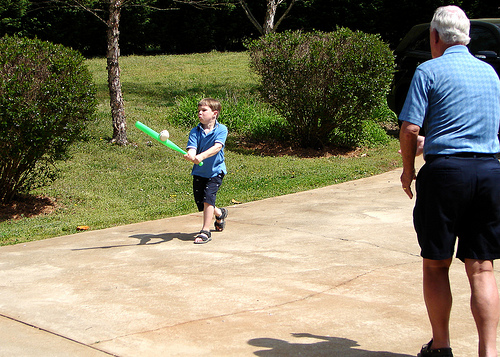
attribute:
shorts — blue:
[189, 168, 225, 211]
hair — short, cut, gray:
[436, 4, 467, 38]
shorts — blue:
[406, 147, 499, 264]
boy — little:
[182, 92, 232, 247]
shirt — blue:
[395, 45, 498, 157]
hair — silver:
[428, 5, 472, 49]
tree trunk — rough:
[106, 1, 126, 149]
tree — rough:
[62, 0, 174, 147]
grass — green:
[99, 176, 144, 199]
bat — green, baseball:
[132, 116, 187, 170]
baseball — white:
[155, 129, 169, 146]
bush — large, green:
[255, 30, 363, 109]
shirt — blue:
[187, 130, 244, 185]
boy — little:
[172, 95, 231, 250]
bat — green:
[131, 120, 202, 167]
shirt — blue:
[183, 125, 231, 180]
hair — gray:
[433, 5, 472, 43]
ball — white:
[159, 128, 169, 141]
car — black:
[388, 14, 499, 135]